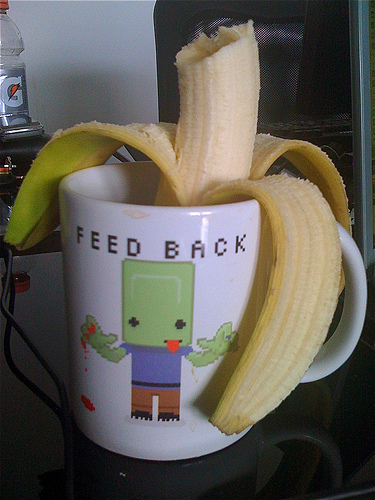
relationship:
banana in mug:
[2, 14, 352, 437] [62, 161, 369, 463]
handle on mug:
[300, 222, 370, 385] [62, 161, 369, 463]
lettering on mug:
[76, 224, 248, 260] [62, 161, 369, 463]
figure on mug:
[77, 258, 240, 426] [62, 161, 369, 463]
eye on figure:
[172, 316, 187, 330] [77, 258, 240, 426]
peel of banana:
[197, 175, 340, 437] [2, 14, 352, 437]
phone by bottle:
[0, 122, 45, 141] [0, 0, 30, 119]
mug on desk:
[62, 161, 369, 463] [2, 218, 373, 495]